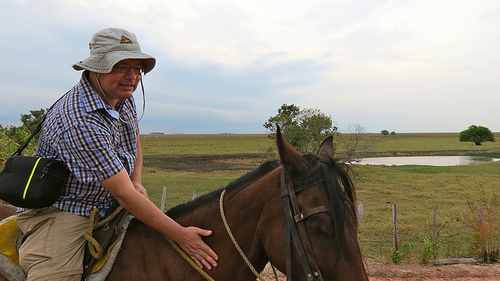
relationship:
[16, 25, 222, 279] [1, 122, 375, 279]
man riding horse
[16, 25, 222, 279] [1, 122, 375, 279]
man petting horse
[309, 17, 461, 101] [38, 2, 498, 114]
clouds in sky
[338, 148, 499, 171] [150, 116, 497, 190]
pond in a field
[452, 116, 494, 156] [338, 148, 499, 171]
tree next to pond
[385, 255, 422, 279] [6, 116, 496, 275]
dirt in field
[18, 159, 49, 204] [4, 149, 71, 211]
stripe on a bag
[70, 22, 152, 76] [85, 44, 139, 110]
hat on head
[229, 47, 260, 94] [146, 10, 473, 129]
part of a cloud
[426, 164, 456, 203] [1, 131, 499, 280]
part of a field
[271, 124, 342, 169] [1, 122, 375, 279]
ears of horse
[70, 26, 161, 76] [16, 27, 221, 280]
hat on man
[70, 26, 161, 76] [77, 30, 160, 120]
hat on head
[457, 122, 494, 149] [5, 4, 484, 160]
tree on background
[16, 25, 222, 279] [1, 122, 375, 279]
man on horse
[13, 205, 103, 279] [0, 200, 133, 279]
cargo pants over saddle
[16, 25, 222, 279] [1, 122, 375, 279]
man patting horse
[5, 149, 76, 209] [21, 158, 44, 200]
bag with stripe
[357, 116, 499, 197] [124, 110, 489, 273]
pond in field